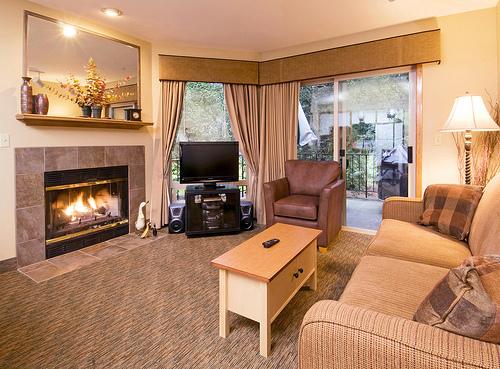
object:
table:
[210, 221, 323, 360]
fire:
[54, 190, 112, 218]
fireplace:
[41, 164, 131, 245]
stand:
[185, 189, 241, 236]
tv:
[178, 141, 241, 183]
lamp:
[437, 96, 499, 187]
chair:
[263, 159, 349, 246]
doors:
[334, 68, 415, 234]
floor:
[1, 221, 377, 368]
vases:
[20, 76, 36, 115]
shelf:
[15, 114, 153, 130]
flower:
[43, 56, 136, 105]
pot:
[91, 106, 103, 118]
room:
[1, 1, 499, 368]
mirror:
[23, 12, 140, 121]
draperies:
[224, 81, 301, 226]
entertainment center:
[168, 180, 254, 237]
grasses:
[455, 89, 499, 185]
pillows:
[416, 184, 485, 241]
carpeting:
[338, 256, 453, 319]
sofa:
[298, 175, 500, 367]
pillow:
[418, 184, 484, 240]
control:
[262, 238, 280, 248]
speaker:
[168, 204, 185, 234]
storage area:
[266, 230, 325, 358]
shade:
[437, 95, 500, 134]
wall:
[0, 2, 156, 263]